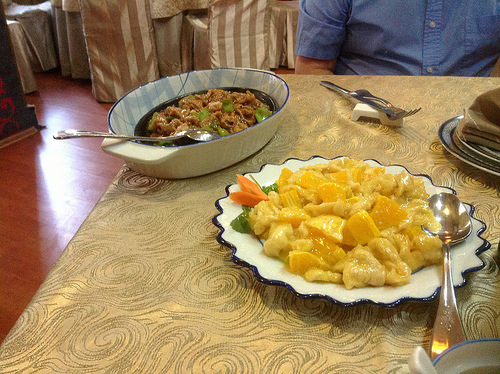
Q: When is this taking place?
A: Daytime.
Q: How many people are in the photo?
A: One.